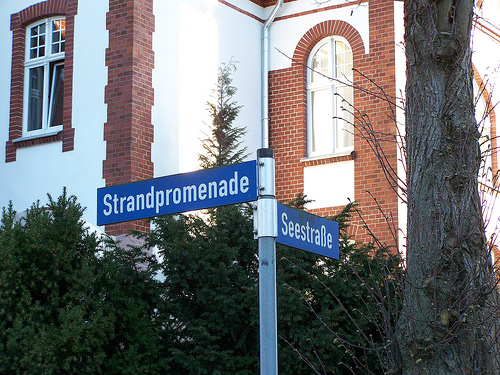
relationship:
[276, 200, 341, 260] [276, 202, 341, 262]
blue street street sign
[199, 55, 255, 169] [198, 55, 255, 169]
small tree branches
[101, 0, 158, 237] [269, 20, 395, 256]
build with bricks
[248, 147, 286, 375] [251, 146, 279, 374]
metal support pole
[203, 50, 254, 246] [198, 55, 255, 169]
green tree in front of building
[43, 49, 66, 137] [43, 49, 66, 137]
window pane open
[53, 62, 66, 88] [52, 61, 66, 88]
white frisbee i someone's hands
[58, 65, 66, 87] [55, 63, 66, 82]
frisbee in hands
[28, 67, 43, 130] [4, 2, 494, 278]
window on building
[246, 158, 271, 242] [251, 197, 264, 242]
bolts on sign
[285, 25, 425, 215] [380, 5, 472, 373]
branches on trunk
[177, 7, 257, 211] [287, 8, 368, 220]
light reflecting on windows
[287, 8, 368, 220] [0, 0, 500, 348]
windows on building